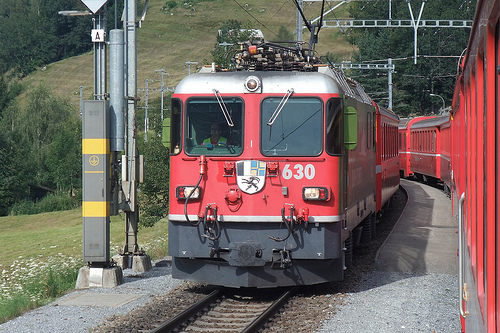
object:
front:
[169, 72, 348, 286]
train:
[168, 71, 399, 292]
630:
[282, 160, 317, 181]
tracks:
[145, 287, 293, 333]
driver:
[200, 123, 229, 151]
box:
[81, 100, 109, 263]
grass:
[0, 202, 169, 321]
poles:
[81, 0, 153, 264]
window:
[184, 97, 240, 155]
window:
[261, 97, 321, 157]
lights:
[178, 187, 328, 203]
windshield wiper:
[211, 89, 232, 127]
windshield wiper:
[263, 86, 301, 128]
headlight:
[181, 187, 199, 200]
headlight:
[299, 188, 323, 200]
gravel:
[0, 269, 467, 333]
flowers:
[0, 230, 167, 301]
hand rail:
[458, 190, 478, 333]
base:
[112, 253, 148, 277]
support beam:
[122, 0, 142, 254]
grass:
[20, 0, 353, 96]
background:
[0, 0, 499, 333]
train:
[400, 0, 500, 332]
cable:
[284, 0, 330, 61]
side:
[0, 92, 163, 333]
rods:
[293, 0, 470, 84]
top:
[275, 0, 470, 119]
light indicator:
[241, 76, 263, 92]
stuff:
[201, 34, 335, 75]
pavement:
[322, 173, 467, 333]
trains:
[167, 0, 495, 333]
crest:
[231, 160, 266, 194]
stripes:
[82, 137, 105, 220]